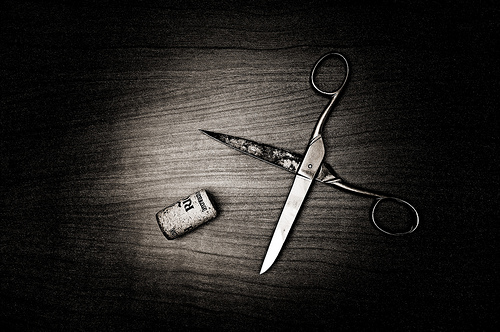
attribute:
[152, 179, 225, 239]
cork — wine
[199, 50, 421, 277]
scissors — metal, open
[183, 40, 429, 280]
scissors — open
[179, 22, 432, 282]
scissors — open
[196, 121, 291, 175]
blade — discolored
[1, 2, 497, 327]
surface — wooden